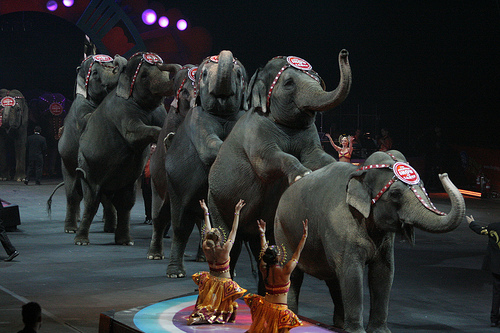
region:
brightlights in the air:
[128, 3, 209, 30]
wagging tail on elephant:
[33, 167, 69, 210]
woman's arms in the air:
[183, 193, 251, 225]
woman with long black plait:
[250, 253, 280, 284]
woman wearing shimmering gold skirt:
[237, 288, 308, 326]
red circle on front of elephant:
[376, 149, 421, 189]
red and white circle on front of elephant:
[249, 59, 299, 92]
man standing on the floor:
[21, 109, 56, 182]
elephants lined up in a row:
[78, 40, 463, 262]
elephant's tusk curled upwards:
[392, 155, 466, 231]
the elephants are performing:
[42, 33, 475, 330]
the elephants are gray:
[34, 37, 441, 328]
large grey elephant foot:
[73, 230, 91, 247]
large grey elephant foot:
[112, 235, 135, 248]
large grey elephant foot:
[62, 219, 74, 231]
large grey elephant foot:
[161, 128, 175, 149]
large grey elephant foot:
[146, 249, 165, 260]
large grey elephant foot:
[161, 260, 188, 280]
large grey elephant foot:
[287, 166, 312, 186]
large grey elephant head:
[342, 148, 469, 250]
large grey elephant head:
[238, 46, 358, 133]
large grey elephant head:
[191, 46, 248, 118]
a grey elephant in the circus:
[273, 150, 464, 332]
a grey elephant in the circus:
[206, 48, 351, 296]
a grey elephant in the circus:
[163, 49, 249, 278]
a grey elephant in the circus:
[148, 64, 197, 261]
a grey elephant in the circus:
[73, 50, 182, 246]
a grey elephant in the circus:
[45, 53, 127, 233]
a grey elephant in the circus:
[1, 88, 28, 182]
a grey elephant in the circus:
[29, 92, 68, 178]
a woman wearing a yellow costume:
[185, 200, 247, 325]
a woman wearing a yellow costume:
[241, 218, 309, 331]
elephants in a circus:
[48, 39, 483, 298]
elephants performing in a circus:
[43, 33, 471, 318]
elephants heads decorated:
[32, 41, 435, 326]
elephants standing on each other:
[103, 50, 453, 326]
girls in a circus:
[164, 164, 375, 326]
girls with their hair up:
[178, 161, 408, 326]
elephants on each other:
[51, 54, 483, 264]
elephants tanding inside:
[44, 46, 385, 315]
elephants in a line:
[19, 26, 486, 326]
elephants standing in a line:
[55, 32, 451, 251]